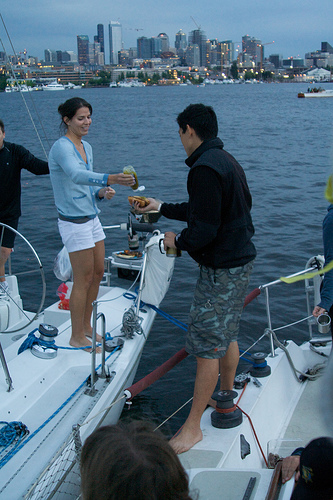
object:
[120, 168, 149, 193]
rellish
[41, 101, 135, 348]
woman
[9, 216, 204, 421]
boat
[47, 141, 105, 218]
top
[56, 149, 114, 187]
longsleeve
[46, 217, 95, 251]
shorts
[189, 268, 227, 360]
shorts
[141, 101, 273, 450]
man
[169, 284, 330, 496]
boats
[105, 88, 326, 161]
ocean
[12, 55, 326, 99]
slyline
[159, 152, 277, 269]
jacket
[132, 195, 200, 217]
hand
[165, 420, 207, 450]
foot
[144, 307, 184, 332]
rope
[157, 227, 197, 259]
hand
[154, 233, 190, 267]
silvermug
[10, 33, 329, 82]
city scape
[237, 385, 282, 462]
redrope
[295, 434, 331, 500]
hat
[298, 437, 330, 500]
head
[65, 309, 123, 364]
barefeet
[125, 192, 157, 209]
bun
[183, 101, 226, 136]
back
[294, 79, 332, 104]
boat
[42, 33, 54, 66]
buildings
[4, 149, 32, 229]
black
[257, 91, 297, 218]
water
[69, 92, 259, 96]
river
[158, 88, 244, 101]
river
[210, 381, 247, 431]
boatties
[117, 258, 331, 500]
on boat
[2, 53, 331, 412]
marina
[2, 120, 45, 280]
people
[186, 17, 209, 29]
crane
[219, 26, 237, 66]
bulding